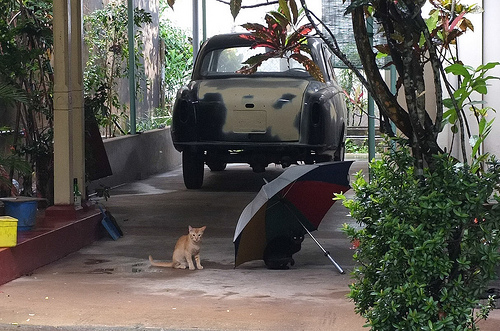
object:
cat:
[149, 225, 207, 270]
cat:
[263, 230, 304, 269]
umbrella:
[233, 161, 355, 273]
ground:
[0, 157, 499, 330]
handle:
[326, 251, 344, 274]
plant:
[168, 0, 499, 330]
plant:
[83, 0, 151, 140]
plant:
[158, 19, 192, 127]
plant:
[0, 0, 56, 196]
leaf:
[446, 64, 470, 88]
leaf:
[419, 197, 428, 209]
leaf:
[86, 73, 89, 78]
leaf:
[0, 83, 11, 93]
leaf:
[188, 54, 190, 57]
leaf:
[393, 289, 402, 294]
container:
[0, 216, 17, 246]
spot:
[241, 35, 256, 40]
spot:
[300, 30, 310, 35]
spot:
[272, 25, 277, 29]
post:
[53, 0, 87, 204]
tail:
[149, 255, 173, 266]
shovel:
[99, 202, 126, 241]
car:
[171, 35, 347, 190]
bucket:
[4, 201, 34, 230]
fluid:
[74, 179, 82, 212]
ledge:
[1, 205, 108, 285]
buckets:
[1, 213, 19, 247]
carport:
[52, 0, 396, 331]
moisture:
[90, 179, 174, 200]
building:
[321, 0, 387, 66]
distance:
[159, 0, 388, 68]